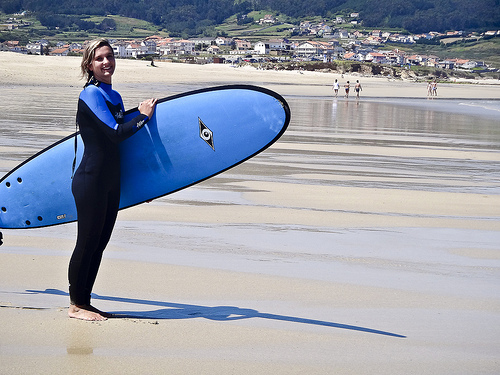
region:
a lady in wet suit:
[64, 35, 154, 327]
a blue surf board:
[1, 85, 294, 231]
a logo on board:
[191, 115, 218, 149]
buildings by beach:
[2, 10, 499, 79]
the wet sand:
[0, 148, 497, 374]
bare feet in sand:
[63, 300, 110, 323]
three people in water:
[326, 76, 363, 97]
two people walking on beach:
[422, 77, 439, 97]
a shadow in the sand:
[21, 285, 405, 338]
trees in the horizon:
[2, 0, 491, 25]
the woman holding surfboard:
[0, 38, 291, 319]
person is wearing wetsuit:
[63, 38, 155, 322]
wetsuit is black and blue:
[69, 80, 151, 307]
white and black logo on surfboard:
[193, 111, 220, 151]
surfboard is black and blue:
[1, 84, 290, 237]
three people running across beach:
[331, 75, 363, 97]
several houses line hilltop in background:
[1, 8, 499, 78]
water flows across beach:
[0, 80, 499, 192]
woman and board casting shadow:
[29, 286, 408, 340]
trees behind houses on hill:
[1, 0, 499, 36]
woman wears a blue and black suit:
[52, 20, 162, 326]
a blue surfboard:
[0, 75, 300, 245]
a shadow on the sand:
[20, 265, 412, 350]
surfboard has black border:
[4, 76, 294, 251]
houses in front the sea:
[118, 12, 498, 114]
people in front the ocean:
[304, 61, 478, 143]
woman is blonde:
[54, 26, 172, 194]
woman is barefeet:
[51, 29, 163, 331]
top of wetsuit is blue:
[67, 81, 164, 181]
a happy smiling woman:
[64, 29, 145, 127]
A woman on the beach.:
[69, 38, 154, 323]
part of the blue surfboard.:
[171, 91, 242, 171]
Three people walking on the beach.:
[331, 78, 363, 98]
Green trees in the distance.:
[153, 8, 188, 24]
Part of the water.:
[477, 104, 497, 113]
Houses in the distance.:
[158, 38, 203, 54]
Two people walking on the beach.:
[428, 82, 438, 98]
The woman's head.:
[79, 36, 116, 84]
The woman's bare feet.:
[67, 304, 106, 320]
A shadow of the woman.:
[98, 295, 258, 324]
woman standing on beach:
[11, 30, 361, 310]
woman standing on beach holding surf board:
[21, 31, 406, 343]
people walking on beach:
[316, 67, 469, 119]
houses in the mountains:
[21, 11, 476, 81]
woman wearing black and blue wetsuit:
[60, 40, 136, 331]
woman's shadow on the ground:
[15, 272, 440, 357]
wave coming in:
[453, 90, 495, 125]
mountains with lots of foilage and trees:
[18, 7, 449, 55]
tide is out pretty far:
[11, 47, 472, 364]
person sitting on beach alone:
[139, 50, 170, 76]